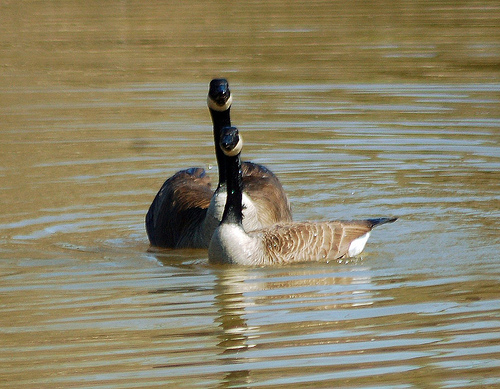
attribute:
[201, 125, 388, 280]
duck — brown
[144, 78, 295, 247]
bird — large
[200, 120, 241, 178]
neck — black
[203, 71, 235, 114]
head — black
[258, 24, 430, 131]
water — calm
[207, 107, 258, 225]
necks — lean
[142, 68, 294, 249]
goose — larger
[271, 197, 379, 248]
feathers — white, brown 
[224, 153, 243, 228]
neck — black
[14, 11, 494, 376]
water — wavy, tranquil, blue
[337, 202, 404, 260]
tail — black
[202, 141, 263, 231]
neck — long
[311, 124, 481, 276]
water — calm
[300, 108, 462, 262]
water — ripply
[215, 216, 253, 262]
feathers — white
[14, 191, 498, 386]
ridges — long, gray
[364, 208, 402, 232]
tail — dark